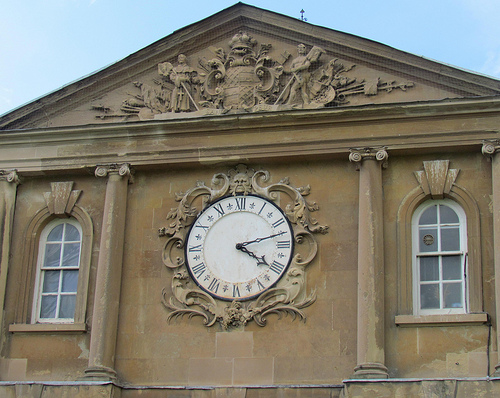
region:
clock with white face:
[177, 183, 299, 301]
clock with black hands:
[174, 188, 304, 310]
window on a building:
[15, 209, 94, 340]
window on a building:
[405, 188, 483, 320]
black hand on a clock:
[234, 224, 288, 249]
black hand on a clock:
[233, 242, 273, 274]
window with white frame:
[400, 193, 475, 325]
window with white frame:
[19, 211, 91, 338]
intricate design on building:
[82, 26, 417, 143]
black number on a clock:
[185, 239, 203, 255]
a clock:
[177, 178, 306, 363]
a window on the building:
[17, 167, 113, 393]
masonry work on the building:
[150, 167, 209, 339]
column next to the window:
[307, 128, 488, 345]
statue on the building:
[145, 39, 230, 131]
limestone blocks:
[121, 197, 218, 396]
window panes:
[37, 231, 61, 266]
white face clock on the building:
[170, 181, 337, 391]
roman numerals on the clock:
[186, 198, 255, 311]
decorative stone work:
[159, 193, 238, 305]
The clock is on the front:
[165, 177, 326, 325]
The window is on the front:
[399, 192, 486, 340]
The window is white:
[408, 195, 494, 352]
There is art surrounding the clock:
[157, 224, 201, 321]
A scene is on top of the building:
[106, 45, 427, 120]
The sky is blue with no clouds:
[9, 3, 81, 58]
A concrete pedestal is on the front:
[343, 151, 395, 376]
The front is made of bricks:
[158, 330, 295, 390]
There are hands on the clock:
[237, 230, 285, 282]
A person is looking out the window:
[410, 215, 447, 257]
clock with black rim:
[177, 190, 300, 307]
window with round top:
[397, 190, 479, 329]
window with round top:
[24, 205, 93, 333]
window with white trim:
[24, 207, 91, 338]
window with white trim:
[403, 191, 480, 318]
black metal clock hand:
[236, 228, 291, 256]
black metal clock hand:
[235, 241, 269, 267]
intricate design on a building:
[86, 31, 415, 142]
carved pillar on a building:
[345, 142, 398, 391]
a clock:
[129, 151, 265, 385]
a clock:
[109, 130, 354, 392]